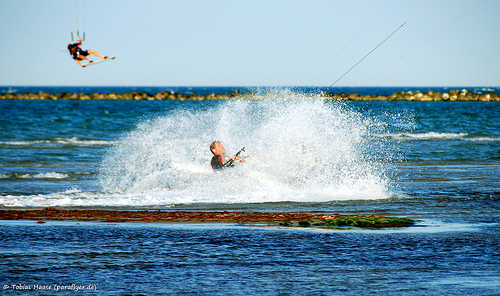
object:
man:
[63, 33, 109, 67]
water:
[1, 86, 498, 292]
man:
[208, 140, 248, 173]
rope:
[240, 1, 500, 155]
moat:
[0, 204, 418, 233]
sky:
[1, 0, 499, 86]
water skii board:
[81, 53, 117, 69]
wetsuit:
[210, 156, 233, 173]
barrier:
[0, 85, 500, 103]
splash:
[94, 84, 423, 209]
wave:
[0, 134, 125, 151]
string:
[72, 0, 78, 38]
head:
[208, 140, 228, 157]